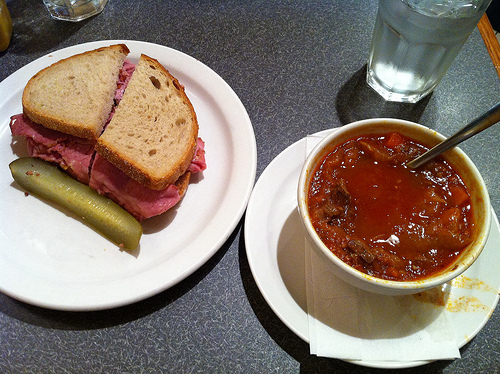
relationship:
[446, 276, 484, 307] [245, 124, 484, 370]
chili on plate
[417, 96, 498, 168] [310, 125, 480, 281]
spoon on chili